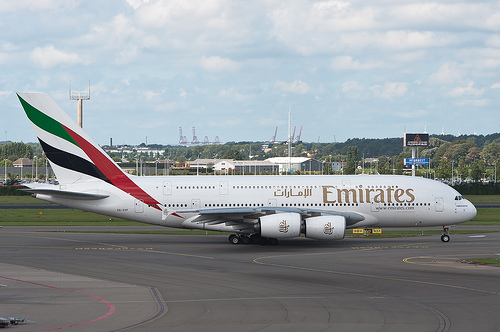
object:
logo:
[15, 90, 188, 221]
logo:
[273, 185, 416, 203]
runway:
[2, 224, 499, 331]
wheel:
[440, 235, 450, 243]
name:
[322, 185, 415, 204]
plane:
[12, 89, 478, 246]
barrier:
[352, 228, 366, 235]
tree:
[478, 139, 499, 184]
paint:
[0, 277, 115, 332]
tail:
[14, 88, 130, 185]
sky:
[0, 0, 499, 147]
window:
[428, 202, 431, 206]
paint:
[402, 256, 478, 271]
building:
[190, 157, 321, 176]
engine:
[302, 215, 345, 240]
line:
[253, 242, 500, 298]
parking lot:
[430, 177, 500, 195]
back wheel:
[229, 234, 240, 245]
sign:
[403, 158, 430, 166]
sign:
[402, 132, 430, 146]